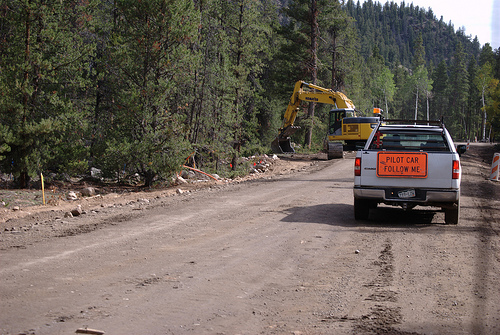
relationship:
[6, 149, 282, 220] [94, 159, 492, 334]
rocks next to road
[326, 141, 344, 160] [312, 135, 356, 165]
middle in middle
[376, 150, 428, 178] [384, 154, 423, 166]
pilot car says pilot car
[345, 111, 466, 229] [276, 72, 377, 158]
car used for construction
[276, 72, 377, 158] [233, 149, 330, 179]
digger used to move dirt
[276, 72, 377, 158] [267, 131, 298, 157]
digger has metal bucket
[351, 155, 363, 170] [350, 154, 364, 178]
light in tail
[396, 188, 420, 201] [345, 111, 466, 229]
license plate on vehicle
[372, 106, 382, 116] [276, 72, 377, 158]
warning light on vehicle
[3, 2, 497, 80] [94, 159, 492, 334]
forest along road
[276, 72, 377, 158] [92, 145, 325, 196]
crane on left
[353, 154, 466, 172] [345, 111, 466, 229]
lights of truck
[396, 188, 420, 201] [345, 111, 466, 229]
license plate of truck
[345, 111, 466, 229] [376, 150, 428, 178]
truck has pilot car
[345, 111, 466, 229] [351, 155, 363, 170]
truck has break light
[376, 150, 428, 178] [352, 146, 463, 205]
pilot car on back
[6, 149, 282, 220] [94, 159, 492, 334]
rocks alongside road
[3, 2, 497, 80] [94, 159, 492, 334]
trees lining street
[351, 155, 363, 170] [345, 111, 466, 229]
light of truck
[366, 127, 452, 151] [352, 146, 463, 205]
window on back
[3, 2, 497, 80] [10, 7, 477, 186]
hillside covered with trees